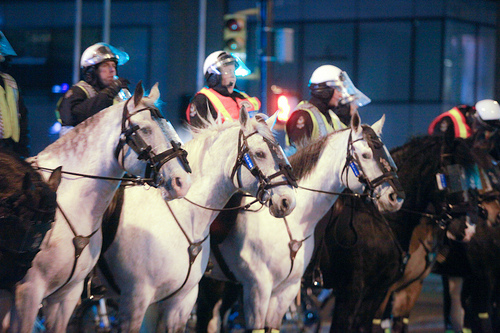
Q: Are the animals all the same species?
A: Yes, all the animals are horses.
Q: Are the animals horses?
A: Yes, all the animals are horses.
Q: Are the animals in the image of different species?
A: No, all the animals are horses.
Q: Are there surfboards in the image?
A: No, there are no surfboards.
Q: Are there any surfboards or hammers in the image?
A: No, there are no surfboards or hammers.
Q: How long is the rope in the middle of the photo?
A: The rope is long.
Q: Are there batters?
A: No, there are no batters.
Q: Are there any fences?
A: No, there are no fences.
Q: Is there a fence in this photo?
A: No, there are no fences.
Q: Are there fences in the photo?
A: No, there are no fences.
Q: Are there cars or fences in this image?
A: No, there are no fences or cars.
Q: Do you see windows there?
A: Yes, there is a window.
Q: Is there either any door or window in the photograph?
A: Yes, there is a window.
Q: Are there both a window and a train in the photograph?
A: No, there is a window but no trains.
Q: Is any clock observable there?
A: No, there are no clocks.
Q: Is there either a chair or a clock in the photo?
A: No, there are no clocks or chairs.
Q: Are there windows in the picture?
A: Yes, there is a window.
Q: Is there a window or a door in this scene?
A: Yes, there is a window.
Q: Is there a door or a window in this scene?
A: Yes, there is a window.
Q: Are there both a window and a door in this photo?
A: No, there is a window but no doors.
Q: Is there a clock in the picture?
A: No, there are no clocks.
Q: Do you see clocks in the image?
A: No, there are no clocks.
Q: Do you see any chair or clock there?
A: No, there are no clocks or chairs.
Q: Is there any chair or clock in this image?
A: No, there are no clocks or chairs.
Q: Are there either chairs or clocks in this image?
A: No, there are no clocks or chairs.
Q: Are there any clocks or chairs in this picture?
A: No, there are no clocks or chairs.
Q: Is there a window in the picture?
A: Yes, there is a window.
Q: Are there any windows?
A: Yes, there is a window.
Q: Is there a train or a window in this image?
A: Yes, there is a window.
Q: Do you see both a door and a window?
A: No, there is a window but no doors.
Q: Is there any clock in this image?
A: No, there are no clocks.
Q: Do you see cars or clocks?
A: No, there are no clocks or cars.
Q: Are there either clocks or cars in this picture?
A: No, there are no clocks or cars.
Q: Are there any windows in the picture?
A: Yes, there is a window.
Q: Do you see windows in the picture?
A: Yes, there is a window.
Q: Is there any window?
A: Yes, there is a window.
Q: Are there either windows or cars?
A: Yes, there is a window.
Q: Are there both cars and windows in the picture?
A: No, there is a window but no cars.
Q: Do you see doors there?
A: No, there are no doors.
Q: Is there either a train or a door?
A: No, there are no doors or trains.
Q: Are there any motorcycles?
A: No, there are no motorcycles.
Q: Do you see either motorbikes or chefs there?
A: No, there are no motorbikes or chefs.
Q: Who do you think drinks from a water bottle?
A: The officer drinks from a water bottle.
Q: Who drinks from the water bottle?
A: The officer drinks from a water bottle.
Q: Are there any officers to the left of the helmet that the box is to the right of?
A: Yes, there is an officer to the left of the helmet.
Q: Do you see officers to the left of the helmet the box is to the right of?
A: Yes, there is an officer to the left of the helmet.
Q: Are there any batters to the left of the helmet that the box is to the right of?
A: No, there is an officer to the left of the helmet.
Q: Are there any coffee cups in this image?
A: No, there are no coffee cups.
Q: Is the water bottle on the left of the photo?
A: Yes, the water bottle is on the left of the image.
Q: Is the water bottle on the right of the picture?
A: No, the water bottle is on the left of the image.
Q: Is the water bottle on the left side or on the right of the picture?
A: The water bottle is on the left of the image.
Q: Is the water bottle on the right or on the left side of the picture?
A: The water bottle is on the left of the image.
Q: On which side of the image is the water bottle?
A: The water bottle is on the left of the image.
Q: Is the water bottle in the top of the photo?
A: Yes, the water bottle is in the top of the image.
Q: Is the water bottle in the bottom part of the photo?
A: No, the water bottle is in the top of the image.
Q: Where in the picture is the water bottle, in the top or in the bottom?
A: The water bottle is in the top of the image.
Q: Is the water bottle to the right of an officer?
A: Yes, the water bottle is to the right of an officer.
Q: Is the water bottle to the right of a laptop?
A: No, the water bottle is to the right of an officer.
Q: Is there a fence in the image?
A: No, there are no fences.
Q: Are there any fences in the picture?
A: No, there are no fences.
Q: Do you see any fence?
A: No, there are no fences.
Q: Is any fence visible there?
A: No, there are no fences.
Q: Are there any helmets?
A: Yes, there is a helmet.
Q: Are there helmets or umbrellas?
A: Yes, there is a helmet.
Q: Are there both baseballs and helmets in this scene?
A: No, there is a helmet but no baseballs.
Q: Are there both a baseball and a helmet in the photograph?
A: No, there is a helmet but no baseballs.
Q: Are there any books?
A: No, there are no books.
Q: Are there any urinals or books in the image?
A: No, there are no books or urinals.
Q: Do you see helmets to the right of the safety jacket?
A: Yes, there is a helmet to the right of the safety jacket.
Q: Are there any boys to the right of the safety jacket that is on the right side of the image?
A: No, there is a helmet to the right of the safety vest.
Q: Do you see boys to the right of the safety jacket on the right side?
A: No, there is a helmet to the right of the safety vest.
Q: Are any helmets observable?
A: Yes, there is a helmet.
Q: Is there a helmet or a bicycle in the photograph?
A: Yes, there is a helmet.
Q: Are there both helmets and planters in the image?
A: No, there is a helmet but no planters.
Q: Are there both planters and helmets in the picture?
A: No, there is a helmet but no planters.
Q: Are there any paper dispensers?
A: No, there are no paper dispensers.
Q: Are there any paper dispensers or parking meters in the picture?
A: No, there are no paper dispensers or parking meters.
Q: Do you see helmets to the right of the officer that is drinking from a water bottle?
A: Yes, there is a helmet to the right of the officer.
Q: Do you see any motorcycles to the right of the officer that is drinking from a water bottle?
A: No, there is a helmet to the right of the officer.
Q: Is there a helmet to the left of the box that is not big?
A: Yes, there is a helmet to the left of the box.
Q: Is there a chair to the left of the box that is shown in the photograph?
A: No, there is a helmet to the left of the box.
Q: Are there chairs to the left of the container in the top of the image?
A: No, there is a helmet to the left of the box.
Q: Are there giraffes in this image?
A: No, there are no giraffes.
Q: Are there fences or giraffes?
A: No, there are no giraffes or fences.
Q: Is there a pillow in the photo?
A: No, there are no pillows.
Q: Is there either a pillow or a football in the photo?
A: No, there are no pillows or footballs.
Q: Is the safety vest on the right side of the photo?
A: Yes, the safety vest is on the right of the image.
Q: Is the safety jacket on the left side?
A: No, the safety jacket is on the right of the image.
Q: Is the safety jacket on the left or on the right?
A: The safety jacket is on the right of the image.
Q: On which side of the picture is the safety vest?
A: The safety vest is on the right of the image.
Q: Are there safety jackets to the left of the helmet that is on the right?
A: Yes, there is a safety jacket to the left of the helmet.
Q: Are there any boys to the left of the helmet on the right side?
A: No, there is a safety jacket to the left of the helmet.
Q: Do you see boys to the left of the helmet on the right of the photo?
A: No, there is a safety jacket to the left of the helmet.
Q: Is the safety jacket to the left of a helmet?
A: Yes, the safety jacket is to the left of a helmet.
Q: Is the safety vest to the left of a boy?
A: No, the safety vest is to the left of a helmet.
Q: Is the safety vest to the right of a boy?
A: No, the safety vest is to the right of the horse.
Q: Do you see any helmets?
A: Yes, there is a helmet.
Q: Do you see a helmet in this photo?
A: Yes, there is a helmet.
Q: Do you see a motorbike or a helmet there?
A: Yes, there is a helmet.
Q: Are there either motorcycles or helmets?
A: Yes, there is a helmet.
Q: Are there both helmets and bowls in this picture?
A: No, there is a helmet but no bowls.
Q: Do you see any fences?
A: No, there are no fences.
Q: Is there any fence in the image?
A: No, there are no fences.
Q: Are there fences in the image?
A: No, there are no fences.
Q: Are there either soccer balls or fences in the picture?
A: No, there are no fences or soccer balls.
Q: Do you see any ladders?
A: No, there are no ladders.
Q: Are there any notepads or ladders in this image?
A: No, there are no ladders or notepads.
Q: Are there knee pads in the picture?
A: No, there are no knee pads.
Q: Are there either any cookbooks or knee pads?
A: No, there are no knee pads or cookbooks.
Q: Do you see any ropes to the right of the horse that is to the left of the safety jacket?
A: No, the rope is to the left of the horse.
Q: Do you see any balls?
A: No, there are no balls.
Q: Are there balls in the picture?
A: No, there are no balls.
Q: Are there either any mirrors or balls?
A: No, there are no balls or mirrors.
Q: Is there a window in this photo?
A: Yes, there is a window.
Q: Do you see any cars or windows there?
A: Yes, there is a window.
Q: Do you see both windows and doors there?
A: No, there is a window but no doors.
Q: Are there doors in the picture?
A: No, there are no doors.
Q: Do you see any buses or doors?
A: No, there are no doors or buses.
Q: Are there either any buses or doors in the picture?
A: No, there are no doors or buses.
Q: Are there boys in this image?
A: No, there are no boys.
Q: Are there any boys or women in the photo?
A: No, there are no boys or women.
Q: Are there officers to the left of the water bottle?
A: Yes, there is an officer to the left of the water bottle.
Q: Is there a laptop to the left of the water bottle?
A: No, there is an officer to the left of the water bottle.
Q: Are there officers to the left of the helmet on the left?
A: Yes, there is an officer to the left of the helmet.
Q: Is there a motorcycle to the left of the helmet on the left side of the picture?
A: No, there is an officer to the left of the helmet.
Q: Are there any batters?
A: No, there are no batters.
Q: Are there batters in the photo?
A: No, there are no batters.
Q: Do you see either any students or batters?
A: No, there are no batters or students.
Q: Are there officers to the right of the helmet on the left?
A: Yes, there is an officer to the right of the helmet.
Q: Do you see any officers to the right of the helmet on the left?
A: Yes, there is an officer to the right of the helmet.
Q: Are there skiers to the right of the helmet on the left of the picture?
A: No, there is an officer to the right of the helmet.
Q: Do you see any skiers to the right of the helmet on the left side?
A: No, there is an officer to the right of the helmet.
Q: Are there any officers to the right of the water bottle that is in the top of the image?
A: Yes, there is an officer to the right of the water bottle.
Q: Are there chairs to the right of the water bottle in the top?
A: No, there is an officer to the right of the water bottle.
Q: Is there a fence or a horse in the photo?
A: Yes, there is a horse.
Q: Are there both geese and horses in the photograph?
A: No, there is a horse but no geese.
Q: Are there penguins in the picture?
A: No, there are no penguins.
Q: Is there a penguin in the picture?
A: No, there are no penguins.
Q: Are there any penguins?
A: No, there are no penguins.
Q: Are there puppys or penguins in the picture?
A: No, there are no penguins or puppys.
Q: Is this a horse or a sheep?
A: This is a horse.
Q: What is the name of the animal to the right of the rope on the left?
A: The animal is a horse.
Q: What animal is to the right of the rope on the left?
A: The animal is a horse.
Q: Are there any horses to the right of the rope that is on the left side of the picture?
A: Yes, there is a horse to the right of the rope.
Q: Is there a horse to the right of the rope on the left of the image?
A: Yes, there is a horse to the right of the rope.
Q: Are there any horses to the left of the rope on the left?
A: No, the horse is to the right of the rope.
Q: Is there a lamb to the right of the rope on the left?
A: No, there is a horse to the right of the rope.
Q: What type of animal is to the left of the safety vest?
A: The animal is a horse.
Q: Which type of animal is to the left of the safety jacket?
A: The animal is a horse.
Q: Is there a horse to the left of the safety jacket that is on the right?
A: Yes, there is a horse to the left of the safety jacket.